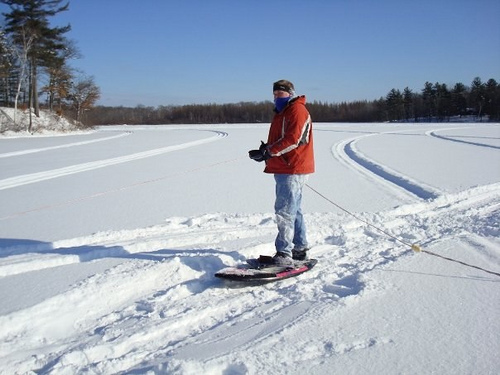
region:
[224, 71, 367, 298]
a man in the snow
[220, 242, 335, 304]
a pink and black board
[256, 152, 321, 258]
a pair of jeans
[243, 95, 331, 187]
a bright orange snow coat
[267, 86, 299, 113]
a bright blue face mask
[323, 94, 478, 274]
some tracks in the snow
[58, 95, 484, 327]
a snow covered field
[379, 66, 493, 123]
a row of evergreen trees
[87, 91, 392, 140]
a forest in the background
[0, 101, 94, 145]
a snow covered slope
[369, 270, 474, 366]
the snow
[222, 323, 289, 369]
the snow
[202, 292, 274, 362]
the snow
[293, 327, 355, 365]
the snow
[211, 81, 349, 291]
person in the snow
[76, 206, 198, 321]
white snow around person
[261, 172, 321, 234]
blue pants on the person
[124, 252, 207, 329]
snow with tracks in it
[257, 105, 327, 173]
red jacket on man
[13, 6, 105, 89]
green tree in the distance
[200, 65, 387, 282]
one person in the snow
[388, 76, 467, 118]
trees far off in the distance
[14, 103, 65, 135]
hill of snow next to trees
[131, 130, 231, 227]
white snow on the ground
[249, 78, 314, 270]
A man standing in snow.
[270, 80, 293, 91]
A black sweatband on a man's head.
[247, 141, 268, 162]
Black gloves on a man's hands.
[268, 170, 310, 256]
Light colored denim jeans on a man.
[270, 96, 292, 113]
Blue bandana over a man's mouth.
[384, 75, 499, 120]
Group of tall pine trees to the upper right.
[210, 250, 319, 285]
Large board in the snow.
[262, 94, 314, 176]
A orange black and white coat a man is wearing.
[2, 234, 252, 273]
Shadow of a man in the snow.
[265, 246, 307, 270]
Black tennis shoes on a man.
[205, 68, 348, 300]
person riding a snowboard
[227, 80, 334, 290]
person wearing blue jeans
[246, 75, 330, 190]
person in a coat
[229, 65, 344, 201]
person with a blue bandana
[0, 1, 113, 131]
a large group of trees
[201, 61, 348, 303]
person wearing gloves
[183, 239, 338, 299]
a snowboard covered in snow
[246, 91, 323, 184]
orange coat with white stripes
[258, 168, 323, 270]
blue jeans covered in snow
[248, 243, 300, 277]
black shoe covered in snow